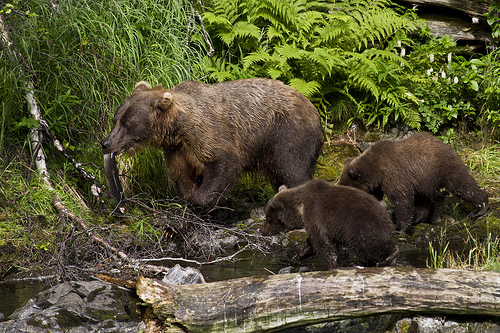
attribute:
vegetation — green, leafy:
[192, 3, 459, 133]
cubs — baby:
[254, 172, 404, 274]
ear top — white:
[163, 90, 175, 101]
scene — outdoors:
[3, 0, 498, 332]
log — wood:
[117, 260, 499, 329]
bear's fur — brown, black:
[260, 94, 299, 136]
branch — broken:
[31, 162, 192, 331]